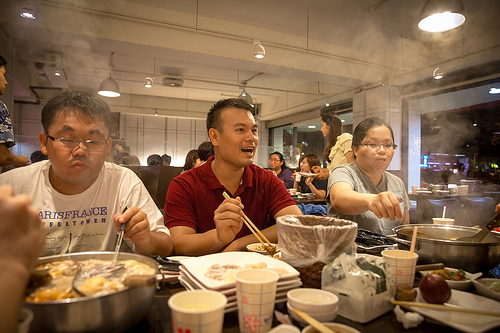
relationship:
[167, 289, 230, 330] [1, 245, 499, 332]
paper cup on table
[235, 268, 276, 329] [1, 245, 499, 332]
paper cup on table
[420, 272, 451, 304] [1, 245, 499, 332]
apple on table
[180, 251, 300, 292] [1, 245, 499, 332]
plate on table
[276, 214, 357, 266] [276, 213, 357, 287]
plastic bag in a basket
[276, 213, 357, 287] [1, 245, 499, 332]
basket on a table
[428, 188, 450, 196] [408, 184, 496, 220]
pan on a stove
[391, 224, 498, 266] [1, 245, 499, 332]
pot on table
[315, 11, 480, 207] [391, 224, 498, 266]
steam coming from pot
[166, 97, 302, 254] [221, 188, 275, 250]
person holding chopstick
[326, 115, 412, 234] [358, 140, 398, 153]
person wearing glasses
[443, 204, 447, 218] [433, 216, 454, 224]
straw in a cup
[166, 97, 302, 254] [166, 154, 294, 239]
person wearing shirt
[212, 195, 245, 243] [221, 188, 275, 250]
hand holds chopstick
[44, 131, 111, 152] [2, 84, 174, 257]
eyeglasses on a person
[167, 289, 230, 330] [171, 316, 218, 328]
paper cup has lines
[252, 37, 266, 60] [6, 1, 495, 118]
lighting on ceiling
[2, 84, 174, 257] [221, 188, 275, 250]
person holding chopstick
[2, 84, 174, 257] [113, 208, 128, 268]
person putting spoon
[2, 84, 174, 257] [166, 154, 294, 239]
person wearing shirt